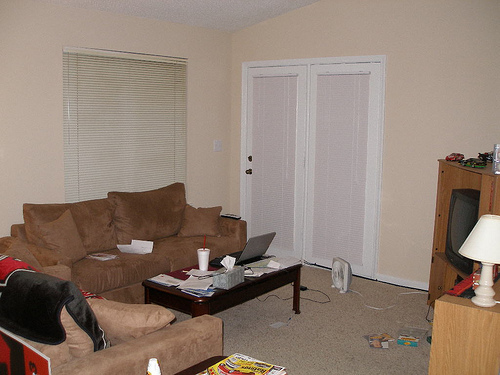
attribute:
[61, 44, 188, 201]
blinds — large set, vertical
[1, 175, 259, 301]
couch — large, brown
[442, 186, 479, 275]
tv — off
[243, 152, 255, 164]
lock — deadbolt lock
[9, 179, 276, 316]
couch — brown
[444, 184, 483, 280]
television — black, small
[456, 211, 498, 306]
table lamp — small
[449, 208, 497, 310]
lamp — white, small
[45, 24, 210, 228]
blinds — down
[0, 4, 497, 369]
room — messy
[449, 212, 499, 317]
lamp — white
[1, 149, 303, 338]
couch — brown, large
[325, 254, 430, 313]
box fan — white, small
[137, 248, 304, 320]
table — brown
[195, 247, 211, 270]
cup — white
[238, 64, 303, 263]
door — white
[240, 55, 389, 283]
door — white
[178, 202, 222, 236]
pillow — brown